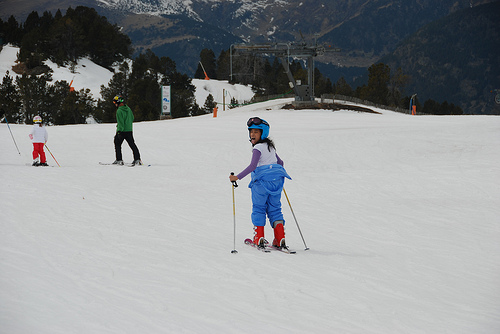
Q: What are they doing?
A: Skiing.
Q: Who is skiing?
A: The kid.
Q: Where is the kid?
A: On the skis.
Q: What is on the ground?
A: Snow.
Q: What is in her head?
A: Helmet.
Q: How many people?
A: 3.